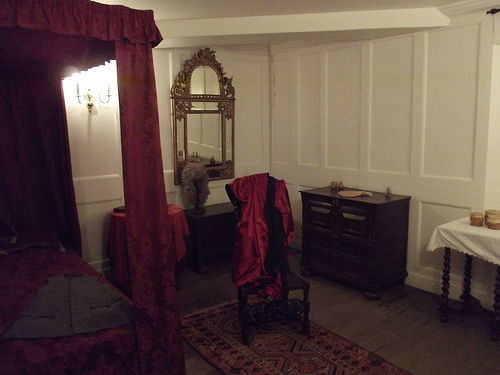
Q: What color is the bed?
A: Red.